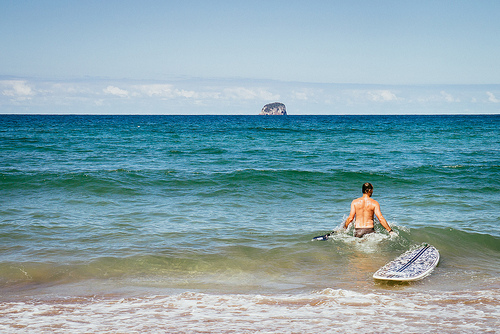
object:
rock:
[255, 98, 293, 115]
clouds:
[377, 88, 397, 102]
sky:
[0, 0, 500, 83]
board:
[371, 240, 442, 283]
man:
[331, 183, 397, 272]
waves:
[50, 170, 150, 198]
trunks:
[351, 225, 377, 238]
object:
[307, 229, 337, 243]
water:
[0, 114, 500, 334]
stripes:
[392, 246, 430, 279]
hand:
[388, 231, 399, 239]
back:
[350, 197, 378, 227]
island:
[0, 214, 500, 334]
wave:
[214, 162, 318, 181]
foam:
[388, 233, 409, 248]